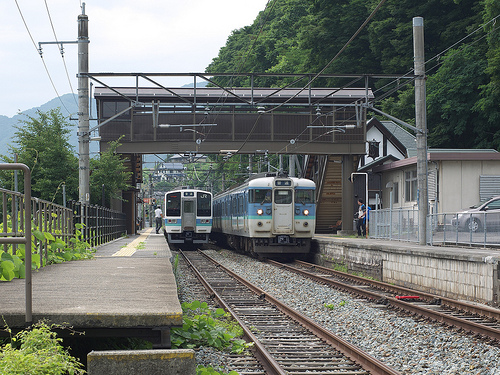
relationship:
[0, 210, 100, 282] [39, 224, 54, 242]
plants with broad leaves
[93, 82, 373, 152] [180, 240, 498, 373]
bridge over train tracks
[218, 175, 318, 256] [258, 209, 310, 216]
train with headlights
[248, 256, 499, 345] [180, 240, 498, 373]
railroad tracks between train tracks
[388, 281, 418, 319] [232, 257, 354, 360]
item on train track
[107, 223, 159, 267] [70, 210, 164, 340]
stripe on sidewalk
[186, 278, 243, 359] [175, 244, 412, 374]
shrub on train track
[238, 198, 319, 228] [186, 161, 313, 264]
lights on bus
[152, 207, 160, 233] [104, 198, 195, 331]
person on sidewalk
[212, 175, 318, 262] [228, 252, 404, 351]
train on tracks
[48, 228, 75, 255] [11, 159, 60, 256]
leaves thru bars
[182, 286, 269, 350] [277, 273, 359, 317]
plant in gravel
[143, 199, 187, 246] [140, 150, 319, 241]
person boarding train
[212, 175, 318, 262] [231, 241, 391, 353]
train on tracks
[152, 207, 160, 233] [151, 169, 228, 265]
person boarding a train